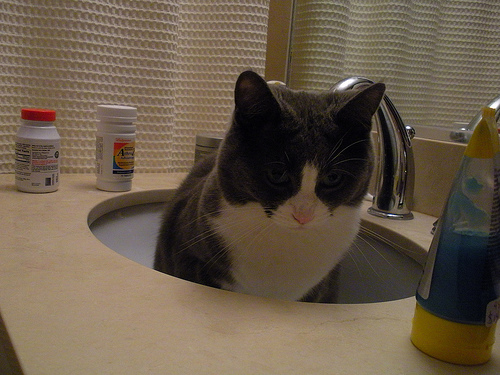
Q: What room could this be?
A: It is a bathroom.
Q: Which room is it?
A: It is a bathroom.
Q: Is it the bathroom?
A: Yes, it is the bathroom.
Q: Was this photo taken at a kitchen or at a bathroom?
A: It was taken at a bathroom.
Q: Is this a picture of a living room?
A: No, the picture is showing a bathroom.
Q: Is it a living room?
A: No, it is a bathroom.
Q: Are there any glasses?
A: No, there are no glasses.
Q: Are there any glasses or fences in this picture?
A: No, there are no glasses or fences.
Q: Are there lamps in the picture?
A: No, there are no lamps.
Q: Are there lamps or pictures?
A: No, there are no lamps or pictures.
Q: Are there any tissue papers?
A: No, there are no tissue papers.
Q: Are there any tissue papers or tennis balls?
A: No, there are no tissue papers or tennis balls.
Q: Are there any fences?
A: No, there are no fences.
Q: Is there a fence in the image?
A: No, there are no fences.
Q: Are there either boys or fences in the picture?
A: No, there are no fences or boys.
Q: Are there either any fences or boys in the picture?
A: No, there are no fences or boys.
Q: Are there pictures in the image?
A: No, there are no pictures.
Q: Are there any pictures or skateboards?
A: No, there are no pictures or skateboards.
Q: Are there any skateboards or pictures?
A: No, there are no pictures or skateboards.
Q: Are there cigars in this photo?
A: No, there are no cigars.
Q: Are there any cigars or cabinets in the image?
A: No, there are no cigars or cabinets.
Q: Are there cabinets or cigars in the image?
A: No, there are no cigars or cabinets.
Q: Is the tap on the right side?
A: Yes, the tap is on the right of the image.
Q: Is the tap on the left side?
A: No, the tap is on the right of the image.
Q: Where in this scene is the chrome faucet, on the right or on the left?
A: The tap is on the right of the image.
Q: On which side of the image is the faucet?
A: The faucet is on the right of the image.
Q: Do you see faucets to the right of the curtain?
A: Yes, there is a faucet to the right of the curtain.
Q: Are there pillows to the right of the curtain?
A: No, there is a faucet to the right of the curtain.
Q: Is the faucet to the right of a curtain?
A: Yes, the faucet is to the right of a curtain.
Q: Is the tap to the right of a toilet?
A: No, the tap is to the right of a curtain.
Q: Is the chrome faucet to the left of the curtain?
A: No, the tap is to the right of the curtain.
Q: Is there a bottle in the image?
A: Yes, there is a bottle.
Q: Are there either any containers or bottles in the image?
A: Yes, there is a bottle.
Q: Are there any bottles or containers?
A: Yes, there is a bottle.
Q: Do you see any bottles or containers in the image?
A: Yes, there is a bottle.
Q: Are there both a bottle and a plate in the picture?
A: No, there is a bottle but no plates.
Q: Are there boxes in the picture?
A: No, there are no boxes.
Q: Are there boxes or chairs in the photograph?
A: No, there are no boxes or chairs.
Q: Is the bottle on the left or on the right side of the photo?
A: The bottle is on the left of the image.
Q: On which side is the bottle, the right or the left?
A: The bottle is on the left of the image.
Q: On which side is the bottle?
A: The bottle is on the left of the image.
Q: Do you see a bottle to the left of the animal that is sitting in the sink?
A: Yes, there is a bottle to the left of the cat.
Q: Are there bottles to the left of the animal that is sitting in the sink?
A: Yes, there is a bottle to the left of the cat.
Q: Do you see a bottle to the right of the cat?
A: No, the bottle is to the left of the cat.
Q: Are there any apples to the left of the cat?
A: No, there is a bottle to the left of the cat.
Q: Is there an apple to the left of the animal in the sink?
A: No, there is a bottle to the left of the cat.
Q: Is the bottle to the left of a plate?
A: No, the bottle is to the left of the cat.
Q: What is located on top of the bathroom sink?
A: The bottle is on top of the sink.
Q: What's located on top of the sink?
A: The bottle is on top of the sink.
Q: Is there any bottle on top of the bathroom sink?
A: Yes, there is a bottle on top of the sink.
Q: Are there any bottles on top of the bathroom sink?
A: Yes, there is a bottle on top of the sink.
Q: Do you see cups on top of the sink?
A: No, there is a bottle on top of the sink.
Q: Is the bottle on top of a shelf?
A: No, the bottle is on top of the sink.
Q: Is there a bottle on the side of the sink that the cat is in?
A: Yes, there is a bottle on the side of the sink.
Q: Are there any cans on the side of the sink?
A: No, there is a bottle on the side of the sink.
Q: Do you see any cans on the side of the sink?
A: No, there is a bottle on the side of the sink.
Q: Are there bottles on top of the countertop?
A: Yes, there is a bottle on top of the countertop.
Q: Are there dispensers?
A: No, there are no dispensers.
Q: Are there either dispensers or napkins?
A: No, there are no dispensers or napkins.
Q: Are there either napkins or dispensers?
A: No, there are no dispensers or napkins.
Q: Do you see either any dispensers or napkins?
A: No, there are no dispensers or napkins.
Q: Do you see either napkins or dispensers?
A: No, there are no dispensers or napkins.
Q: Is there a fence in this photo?
A: No, there are no fences.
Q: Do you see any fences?
A: No, there are no fences.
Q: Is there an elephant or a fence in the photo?
A: No, there are no fences or elephants.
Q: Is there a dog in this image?
A: No, there are no dogs.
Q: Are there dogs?
A: No, there are no dogs.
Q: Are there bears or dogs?
A: No, there are no dogs or bears.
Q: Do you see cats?
A: Yes, there is a cat.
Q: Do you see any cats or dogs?
A: Yes, there is a cat.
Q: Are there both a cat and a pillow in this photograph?
A: No, there is a cat but no pillows.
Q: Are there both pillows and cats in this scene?
A: No, there is a cat but no pillows.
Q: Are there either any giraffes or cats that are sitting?
A: Yes, the cat is sitting.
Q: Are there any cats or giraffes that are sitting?
A: Yes, the cat is sitting.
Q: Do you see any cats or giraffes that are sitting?
A: Yes, the cat is sitting.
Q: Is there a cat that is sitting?
A: Yes, there is a cat that is sitting.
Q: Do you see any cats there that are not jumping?
A: Yes, there is a cat that is sitting .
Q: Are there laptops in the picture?
A: No, there are no laptops.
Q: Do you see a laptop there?
A: No, there are no laptops.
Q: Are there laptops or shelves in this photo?
A: No, there are no laptops or shelves.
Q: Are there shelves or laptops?
A: No, there are no laptops or shelves.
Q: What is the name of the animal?
A: The animal is a cat.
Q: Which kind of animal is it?
A: The animal is a cat.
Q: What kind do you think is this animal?
A: This is a cat.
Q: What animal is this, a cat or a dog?
A: This is a cat.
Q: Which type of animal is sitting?
A: The animal is a cat.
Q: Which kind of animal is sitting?
A: The animal is a cat.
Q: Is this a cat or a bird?
A: This is a cat.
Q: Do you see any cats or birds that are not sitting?
A: No, there is a cat but it is sitting.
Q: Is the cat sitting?
A: Yes, the cat is sitting.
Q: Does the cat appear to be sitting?
A: Yes, the cat is sitting.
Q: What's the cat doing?
A: The cat is sitting.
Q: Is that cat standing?
A: No, the cat is sitting.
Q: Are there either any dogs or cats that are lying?
A: No, there is a cat but it is sitting.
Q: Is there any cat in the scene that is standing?
A: No, there is a cat but it is sitting.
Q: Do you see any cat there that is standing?
A: No, there is a cat but it is sitting.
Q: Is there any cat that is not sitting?
A: No, there is a cat but it is sitting.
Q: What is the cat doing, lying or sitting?
A: The cat is sitting.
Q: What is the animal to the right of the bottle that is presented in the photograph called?
A: The animal is a cat.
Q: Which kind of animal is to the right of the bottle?
A: The animal is a cat.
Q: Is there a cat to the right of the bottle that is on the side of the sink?
A: Yes, there is a cat to the right of the bottle.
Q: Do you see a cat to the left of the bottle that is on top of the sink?
A: No, the cat is to the right of the bottle.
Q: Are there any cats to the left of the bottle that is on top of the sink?
A: No, the cat is to the right of the bottle.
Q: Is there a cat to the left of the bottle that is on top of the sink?
A: No, the cat is to the right of the bottle.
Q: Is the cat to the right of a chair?
A: No, the cat is to the right of the bottle.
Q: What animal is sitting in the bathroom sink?
A: The cat is sitting in the sink.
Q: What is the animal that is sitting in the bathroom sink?
A: The animal is a cat.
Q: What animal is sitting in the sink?
A: The animal is a cat.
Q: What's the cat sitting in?
A: The cat is sitting in the sink.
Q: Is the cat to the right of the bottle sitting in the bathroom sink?
A: Yes, the cat is sitting in the sink.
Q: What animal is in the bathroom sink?
A: The animal is a cat.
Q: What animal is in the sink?
A: The animal is a cat.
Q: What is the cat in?
A: The cat is in the sink.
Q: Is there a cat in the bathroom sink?
A: Yes, there is a cat in the sink.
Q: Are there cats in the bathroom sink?
A: Yes, there is a cat in the sink.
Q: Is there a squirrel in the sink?
A: No, there is a cat in the sink.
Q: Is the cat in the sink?
A: Yes, the cat is in the sink.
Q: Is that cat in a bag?
A: No, the cat is in the sink.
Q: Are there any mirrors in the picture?
A: Yes, there is a mirror.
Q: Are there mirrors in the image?
A: Yes, there is a mirror.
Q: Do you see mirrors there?
A: Yes, there is a mirror.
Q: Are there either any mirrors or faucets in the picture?
A: Yes, there is a mirror.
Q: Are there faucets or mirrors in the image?
A: Yes, there is a mirror.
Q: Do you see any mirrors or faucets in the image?
A: Yes, there is a mirror.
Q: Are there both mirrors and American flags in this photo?
A: No, there is a mirror but no American flags.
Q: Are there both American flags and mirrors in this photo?
A: No, there is a mirror but no American flags.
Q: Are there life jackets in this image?
A: No, there are no life jackets.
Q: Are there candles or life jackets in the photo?
A: No, there are no life jackets or candles.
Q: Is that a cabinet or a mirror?
A: That is a mirror.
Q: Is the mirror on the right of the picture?
A: Yes, the mirror is on the right of the image.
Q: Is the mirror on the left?
A: No, the mirror is on the right of the image.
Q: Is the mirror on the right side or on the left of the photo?
A: The mirror is on the right of the image.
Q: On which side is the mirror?
A: The mirror is on the right of the image.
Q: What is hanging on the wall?
A: The mirror is hanging on the wall.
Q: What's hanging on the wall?
A: The mirror is hanging on the wall.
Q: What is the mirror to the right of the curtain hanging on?
A: The mirror is hanging on the wall.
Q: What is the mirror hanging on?
A: The mirror is hanging on the wall.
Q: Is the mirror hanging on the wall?
A: Yes, the mirror is hanging on the wall.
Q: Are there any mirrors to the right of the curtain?
A: Yes, there is a mirror to the right of the curtain.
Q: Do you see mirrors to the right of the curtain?
A: Yes, there is a mirror to the right of the curtain.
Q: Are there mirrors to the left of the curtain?
A: No, the mirror is to the right of the curtain.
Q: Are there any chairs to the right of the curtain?
A: No, there is a mirror to the right of the curtain.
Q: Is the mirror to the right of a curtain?
A: Yes, the mirror is to the right of a curtain.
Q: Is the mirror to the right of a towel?
A: No, the mirror is to the right of a curtain.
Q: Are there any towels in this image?
A: No, there are no towels.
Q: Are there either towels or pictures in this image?
A: No, there are no towels or pictures.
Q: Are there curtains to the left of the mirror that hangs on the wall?
A: Yes, there is a curtain to the left of the mirror.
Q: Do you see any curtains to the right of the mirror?
A: No, the curtain is to the left of the mirror.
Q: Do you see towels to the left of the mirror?
A: No, there is a curtain to the left of the mirror.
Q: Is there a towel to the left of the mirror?
A: No, there is a curtain to the left of the mirror.